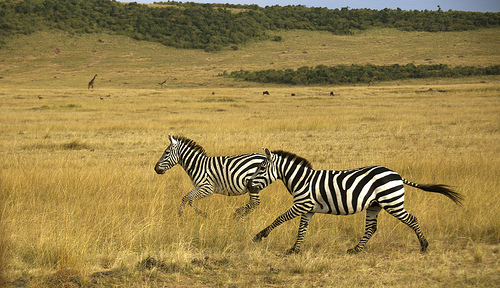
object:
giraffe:
[87, 73, 99, 89]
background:
[4, 29, 495, 93]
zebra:
[247, 148, 468, 255]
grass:
[0, 86, 495, 286]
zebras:
[154, 132, 274, 221]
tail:
[401, 177, 466, 207]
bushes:
[1, 0, 110, 44]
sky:
[209, 1, 498, 26]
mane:
[270, 148, 313, 169]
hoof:
[251, 233, 269, 242]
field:
[7, 32, 498, 283]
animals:
[263, 91, 271, 96]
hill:
[1, 1, 500, 69]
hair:
[419, 181, 468, 208]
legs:
[377, 199, 430, 255]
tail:
[86, 83, 88, 86]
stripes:
[309, 168, 335, 216]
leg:
[251, 201, 315, 243]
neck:
[90, 76, 96, 81]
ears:
[264, 148, 273, 162]